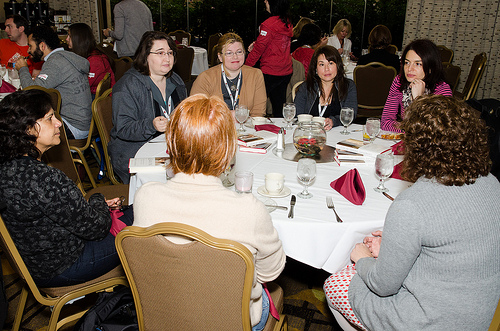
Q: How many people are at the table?
A: Seven.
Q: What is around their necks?
A: Lanyards.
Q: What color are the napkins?
A: Pink.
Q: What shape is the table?
A: Round.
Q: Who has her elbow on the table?
A: The woman in pink.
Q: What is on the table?
A: Glasses.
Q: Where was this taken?
A: Inside a convention center.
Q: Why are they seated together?
A: To talk.